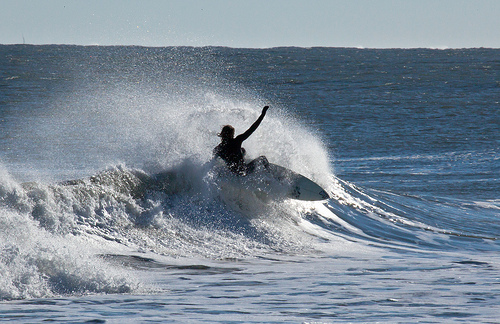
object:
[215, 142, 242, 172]
body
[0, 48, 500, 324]
water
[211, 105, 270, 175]
person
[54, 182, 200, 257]
wave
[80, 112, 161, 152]
spray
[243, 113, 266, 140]
arm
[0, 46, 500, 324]
ocean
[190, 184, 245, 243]
suds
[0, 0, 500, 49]
sky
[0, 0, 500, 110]
background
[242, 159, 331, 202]
board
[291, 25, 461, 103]
edge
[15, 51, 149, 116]
side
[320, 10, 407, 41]
part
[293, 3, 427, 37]
cloud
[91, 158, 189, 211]
ripples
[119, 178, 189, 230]
surface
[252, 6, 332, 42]
air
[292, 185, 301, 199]
design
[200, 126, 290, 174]
sufer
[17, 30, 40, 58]
boat